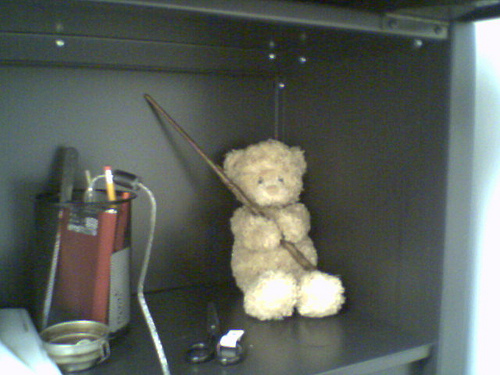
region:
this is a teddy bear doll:
[225, 140, 322, 325]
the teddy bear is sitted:
[223, 141, 340, 308]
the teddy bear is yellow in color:
[228, 139, 350, 321]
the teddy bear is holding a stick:
[155, 91, 253, 200]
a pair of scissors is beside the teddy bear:
[179, 300, 236, 372]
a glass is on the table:
[35, 198, 138, 308]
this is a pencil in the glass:
[97, 165, 116, 200]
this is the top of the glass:
[46, 320, 111, 357]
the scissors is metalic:
[199, 305, 227, 374]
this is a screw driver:
[50, 145, 77, 198]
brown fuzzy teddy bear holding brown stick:
[133, 86, 346, 326]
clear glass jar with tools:
[33, 132, 155, 357]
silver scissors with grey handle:
[178, 292, 250, 369]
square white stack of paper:
[0, 295, 66, 369]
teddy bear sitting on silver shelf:
[218, 130, 354, 322]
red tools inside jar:
[53, 185, 138, 331]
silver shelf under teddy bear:
[14, 253, 441, 371]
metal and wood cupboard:
[4, 1, 496, 371]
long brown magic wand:
[140, 85, 327, 273]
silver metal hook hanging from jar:
[84, 165, 211, 373]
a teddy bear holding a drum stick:
[142, 78, 371, 326]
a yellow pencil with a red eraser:
[98, 161, 127, 203]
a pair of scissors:
[176, 301, 248, 371]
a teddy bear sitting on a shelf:
[208, 119, 389, 373]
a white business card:
[91, 237, 139, 349]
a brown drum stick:
[160, 85, 315, 285]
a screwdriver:
[15, 140, 89, 325]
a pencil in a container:
[23, 146, 164, 336]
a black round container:
[16, 181, 180, 353]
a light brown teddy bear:
[232, 125, 337, 337]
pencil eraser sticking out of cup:
[87, 159, 128, 201]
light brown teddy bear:
[231, 125, 360, 332]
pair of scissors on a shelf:
[177, 290, 249, 372]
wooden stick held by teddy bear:
[135, 82, 328, 273]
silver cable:
[133, 183, 185, 371]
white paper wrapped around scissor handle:
[215, 317, 254, 352]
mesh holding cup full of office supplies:
[16, 176, 138, 348]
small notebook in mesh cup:
[50, 201, 117, 331]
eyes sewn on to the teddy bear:
[252, 168, 302, 185]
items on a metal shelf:
[4, 2, 478, 372]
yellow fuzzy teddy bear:
[208, 135, 370, 325]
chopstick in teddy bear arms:
[139, 88, 342, 283]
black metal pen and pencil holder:
[21, 134, 156, 353]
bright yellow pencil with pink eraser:
[98, 155, 125, 207]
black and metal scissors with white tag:
[168, 291, 250, 371]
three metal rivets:
[258, 47, 316, 93]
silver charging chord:
[131, 172, 183, 373]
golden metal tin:
[37, 320, 117, 362]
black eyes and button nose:
[250, 172, 304, 204]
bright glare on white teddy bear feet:
[238, 269, 371, 329]